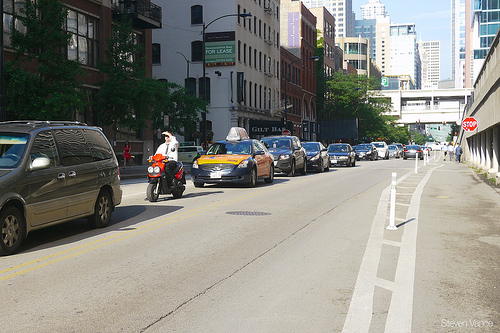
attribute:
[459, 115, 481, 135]
sign — red, white, octagon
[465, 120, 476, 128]
stop — white, printed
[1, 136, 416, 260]
street — sunny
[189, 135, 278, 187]
car — yellow, black, taxi, cab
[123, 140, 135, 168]
woman — walking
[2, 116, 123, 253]
minivan — grey, leading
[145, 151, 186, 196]
scooter — orange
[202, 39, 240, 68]
sign — green, white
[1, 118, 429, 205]
vehicles — stuck in traffic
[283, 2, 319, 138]
building — brick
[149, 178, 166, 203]
tire — black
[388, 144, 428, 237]
dividers — white